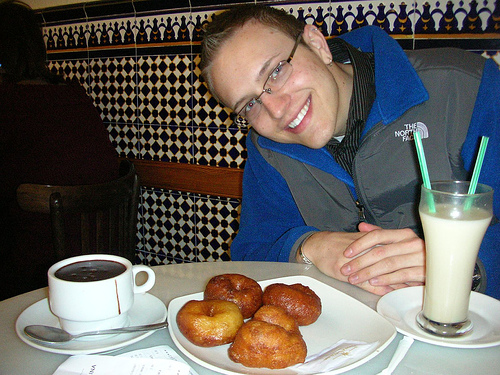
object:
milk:
[419, 203, 493, 324]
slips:
[69, 337, 197, 375]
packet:
[294, 337, 380, 373]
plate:
[14, 292, 166, 356]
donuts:
[175, 273, 320, 369]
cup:
[47, 254, 156, 342]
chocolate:
[54, 259, 126, 282]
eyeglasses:
[233, 30, 303, 127]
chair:
[15, 160, 137, 265]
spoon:
[24, 323, 168, 344]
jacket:
[230, 25, 500, 299]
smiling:
[251, 81, 325, 148]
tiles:
[111, 54, 149, 114]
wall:
[132, 130, 184, 210]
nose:
[263, 92, 291, 120]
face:
[214, 32, 339, 149]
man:
[195, 7, 500, 303]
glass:
[417, 182, 494, 336]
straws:
[413, 131, 490, 213]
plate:
[165, 273, 397, 375]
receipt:
[51, 343, 196, 375]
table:
[0, 260, 500, 375]